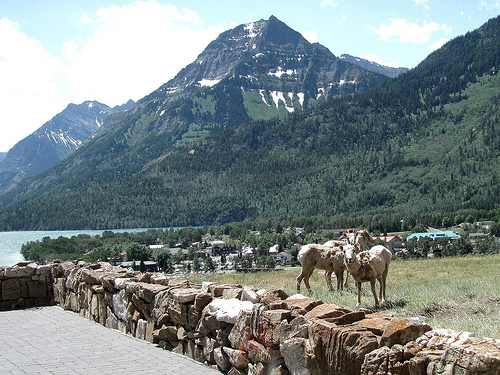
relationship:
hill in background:
[297, 110, 338, 169] [35, 10, 480, 221]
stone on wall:
[373, 311, 436, 347] [54, 259, 460, 373]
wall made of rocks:
[54, 259, 460, 373] [84, 269, 224, 331]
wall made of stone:
[0, 261, 500, 375] [373, 311, 436, 347]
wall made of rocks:
[54, 259, 460, 373] [3, 269, 58, 311]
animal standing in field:
[333, 243, 392, 311] [147, 252, 497, 350]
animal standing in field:
[293, 227, 366, 297] [147, 252, 497, 350]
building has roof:
[405, 227, 460, 254] [405, 230, 459, 242]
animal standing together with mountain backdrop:
[333, 243, 392, 311] [0, 10, 499, 235]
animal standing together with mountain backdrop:
[344, 237, 390, 306] [0, 10, 499, 235]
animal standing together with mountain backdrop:
[293, 227, 366, 297] [0, 10, 499, 235]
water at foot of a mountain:
[0, 212, 225, 289] [0, 15, 496, 229]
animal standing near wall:
[344, 237, 390, 306] [0, 261, 500, 375]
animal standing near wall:
[293, 237, 355, 296] [0, 261, 500, 375]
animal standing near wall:
[333, 243, 392, 311] [0, 261, 500, 375]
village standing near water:
[190, 209, 487, 294] [0, 229, 223, 372]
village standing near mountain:
[190, 209, 487, 294] [0, 15, 496, 229]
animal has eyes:
[333, 243, 392, 311] [341, 243, 358, 257]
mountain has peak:
[0, 19, 402, 225] [208, 3, 324, 71]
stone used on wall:
[373, 311, 436, 347] [0, 262, 497, 374]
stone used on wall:
[193, 291, 213, 312] [0, 262, 497, 374]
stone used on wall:
[142, 282, 167, 304] [54, 259, 460, 373]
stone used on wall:
[144, 323, 154, 340] [0, 262, 497, 374]